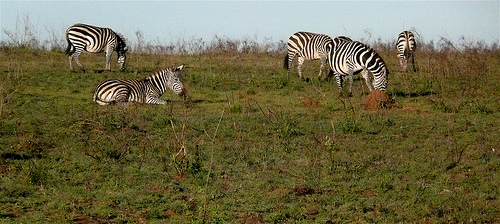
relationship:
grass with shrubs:
[52, 101, 375, 220] [68, 103, 381, 221]